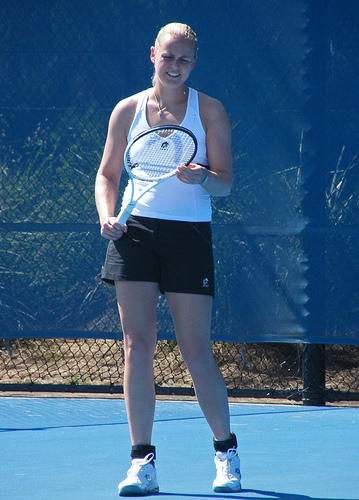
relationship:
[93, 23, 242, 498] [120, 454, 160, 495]
woman has tennis shoe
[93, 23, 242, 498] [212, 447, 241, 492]
woman has tennis shoe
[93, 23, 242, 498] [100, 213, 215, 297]
woman wearing shorts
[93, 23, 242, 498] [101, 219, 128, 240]
woman has hand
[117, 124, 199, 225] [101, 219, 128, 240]
tennis racket in hand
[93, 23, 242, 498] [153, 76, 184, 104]
woman has neck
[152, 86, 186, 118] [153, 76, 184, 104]
necklace around neck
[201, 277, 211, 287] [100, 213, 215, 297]
logo on shorts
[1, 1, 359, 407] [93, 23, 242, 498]
fence behind woman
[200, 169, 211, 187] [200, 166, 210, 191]
watch on wrist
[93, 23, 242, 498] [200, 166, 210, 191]
woman has wrist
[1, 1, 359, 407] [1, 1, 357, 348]
fence has netting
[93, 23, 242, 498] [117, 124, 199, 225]
woman holding tennis racket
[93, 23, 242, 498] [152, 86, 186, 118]
woman has necklace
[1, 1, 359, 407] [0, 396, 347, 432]
fence has shadow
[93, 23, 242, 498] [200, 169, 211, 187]
woman has bracelet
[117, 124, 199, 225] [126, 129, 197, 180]
tennis racket has strings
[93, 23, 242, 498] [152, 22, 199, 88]
woman has hair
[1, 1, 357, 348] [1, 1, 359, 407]
netting on fence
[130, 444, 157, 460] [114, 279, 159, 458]
ankle weight on leg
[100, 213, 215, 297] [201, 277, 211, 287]
shorts have logo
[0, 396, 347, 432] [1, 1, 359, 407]
shadow of fence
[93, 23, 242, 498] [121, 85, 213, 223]
woman wearing tank top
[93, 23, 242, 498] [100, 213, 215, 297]
woman has shorts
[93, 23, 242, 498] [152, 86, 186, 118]
woman wearing necklace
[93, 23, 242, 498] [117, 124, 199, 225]
woman looking at tennis racket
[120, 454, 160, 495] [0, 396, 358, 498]
tennis shoe on tennis court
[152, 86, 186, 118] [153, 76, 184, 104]
necklace on neck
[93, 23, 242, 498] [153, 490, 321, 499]
woman has shadow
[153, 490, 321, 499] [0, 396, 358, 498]
shadow on tennis court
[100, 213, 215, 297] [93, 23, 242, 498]
shorts on woman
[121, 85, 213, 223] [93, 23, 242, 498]
tank top on woman